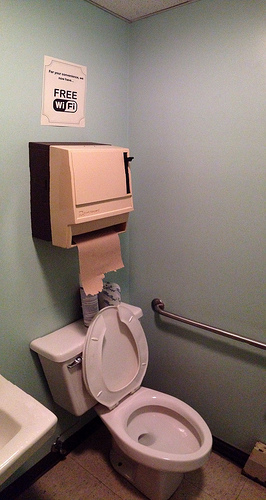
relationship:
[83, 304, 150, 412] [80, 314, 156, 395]
lid of seat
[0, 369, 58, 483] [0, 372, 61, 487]
bathroom sink of sink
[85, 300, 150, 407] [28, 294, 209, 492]
lid of toilet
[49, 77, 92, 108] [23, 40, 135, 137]
word on sign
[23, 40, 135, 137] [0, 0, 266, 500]
sign above bathroom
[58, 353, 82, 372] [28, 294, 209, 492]
handle on toilet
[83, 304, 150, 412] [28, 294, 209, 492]
lid on toilet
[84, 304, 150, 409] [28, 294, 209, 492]
seat on toilet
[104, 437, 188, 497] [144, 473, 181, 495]
base on toilet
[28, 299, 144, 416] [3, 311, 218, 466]
water bowl on toilet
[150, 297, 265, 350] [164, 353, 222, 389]
bar on wall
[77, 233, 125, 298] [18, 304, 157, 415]
paper on water bowl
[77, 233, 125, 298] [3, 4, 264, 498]
paper in bathroom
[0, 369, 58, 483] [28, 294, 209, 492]
bathroom sink next to toilet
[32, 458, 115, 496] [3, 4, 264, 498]
floor in bathroom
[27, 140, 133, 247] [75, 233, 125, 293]
dispenser of paper